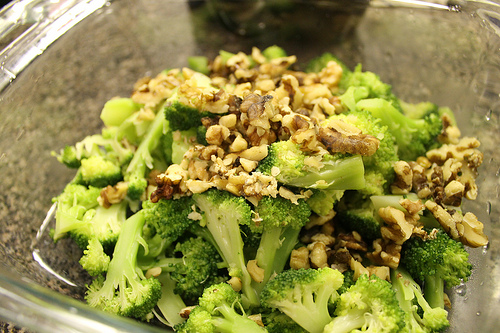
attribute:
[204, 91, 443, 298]
broccoli — green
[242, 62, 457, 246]
veggie — green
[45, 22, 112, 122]
bowl — clear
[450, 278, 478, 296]
water — drops